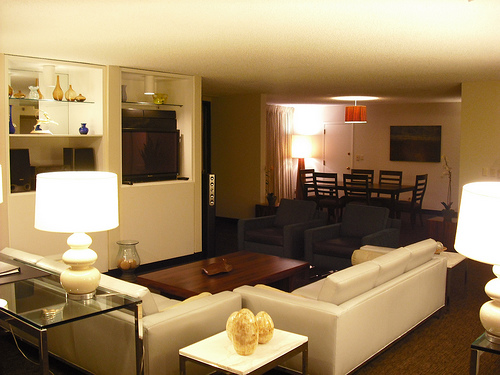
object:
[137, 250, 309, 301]
table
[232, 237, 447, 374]
sofa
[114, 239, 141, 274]
vase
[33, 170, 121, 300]
lamp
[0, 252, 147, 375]
table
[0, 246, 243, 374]
sofa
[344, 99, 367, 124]
light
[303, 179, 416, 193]
dining table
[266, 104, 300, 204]
curtain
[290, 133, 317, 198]
light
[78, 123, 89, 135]
vase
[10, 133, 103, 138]
shelf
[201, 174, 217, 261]
speaker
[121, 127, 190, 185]
television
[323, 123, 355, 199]
door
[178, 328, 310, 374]
end table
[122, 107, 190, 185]
entertainment center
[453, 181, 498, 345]
lamp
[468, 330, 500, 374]
table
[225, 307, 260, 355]
sculpture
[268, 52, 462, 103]
ceiling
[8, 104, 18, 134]
bottle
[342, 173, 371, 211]
chairs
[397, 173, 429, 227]
chairs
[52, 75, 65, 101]
bottles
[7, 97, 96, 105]
shelf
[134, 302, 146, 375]
leg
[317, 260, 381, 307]
cushion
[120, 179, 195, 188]
shelf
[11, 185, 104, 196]
shelves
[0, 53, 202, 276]
wall